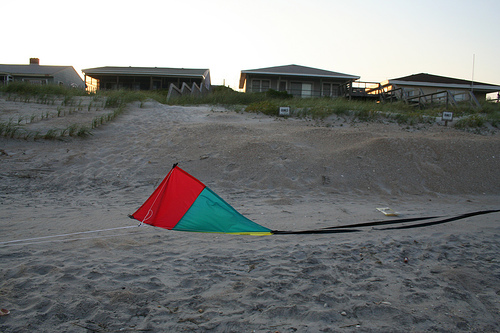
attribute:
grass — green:
[0, 78, 499, 129]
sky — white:
[0, 2, 497, 102]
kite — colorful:
[128, 161, 273, 239]